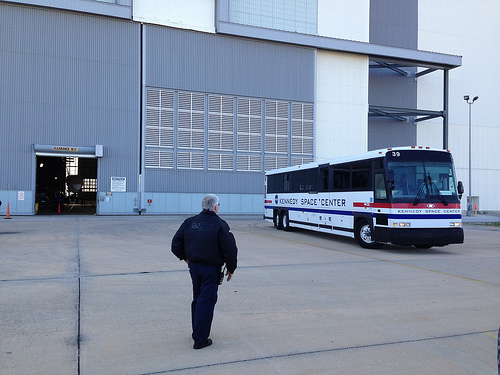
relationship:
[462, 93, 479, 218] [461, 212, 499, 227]
light in sidewalk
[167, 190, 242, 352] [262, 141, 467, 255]
bus driver in bus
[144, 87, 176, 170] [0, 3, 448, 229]
window in building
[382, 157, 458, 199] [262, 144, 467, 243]
windshield in bus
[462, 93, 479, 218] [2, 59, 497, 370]
light in parking lot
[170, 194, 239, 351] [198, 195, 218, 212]
bus driver in hair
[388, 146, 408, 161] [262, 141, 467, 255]
number in bus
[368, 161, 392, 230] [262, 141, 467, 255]
door of bus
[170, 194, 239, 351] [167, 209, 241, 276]
bus driver with jacket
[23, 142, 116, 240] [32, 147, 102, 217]
garage has door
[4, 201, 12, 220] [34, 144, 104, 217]
cone left garage door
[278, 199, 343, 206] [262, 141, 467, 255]
words side bus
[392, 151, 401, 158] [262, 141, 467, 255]
number above bus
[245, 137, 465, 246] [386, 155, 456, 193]
bus has windshield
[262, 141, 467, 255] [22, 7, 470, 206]
bus in front of building